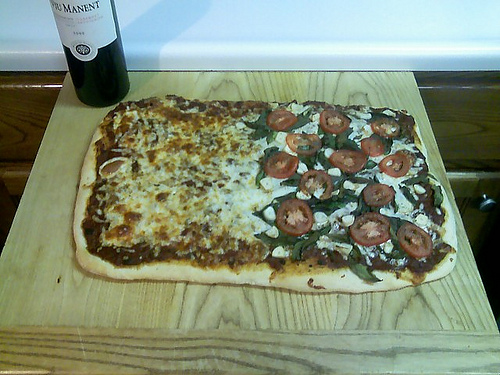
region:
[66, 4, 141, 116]
wine bottle on table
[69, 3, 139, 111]
wine bottle is red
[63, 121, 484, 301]
brown crust of pizza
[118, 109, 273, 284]
yellow cheese on pizza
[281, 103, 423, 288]
red tomatoes on pizza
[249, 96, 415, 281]
green basil on pizza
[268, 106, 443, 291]
white nuts on pizza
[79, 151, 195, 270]
red sauce on pizza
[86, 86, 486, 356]
board is light brown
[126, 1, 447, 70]
white counter behind board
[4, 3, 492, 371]
rectangle shaped pizza and a bottle of wine on a large wooden board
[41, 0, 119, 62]
white label on a dark glass bottle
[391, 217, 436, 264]
slice of tomato and greens on rectangle pizza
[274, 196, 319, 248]
slice of tomato and greens on rectangle pizza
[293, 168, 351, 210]
slice of tomato and greens on rectangle pizza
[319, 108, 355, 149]
slice of tomato and greens on rectangle pizza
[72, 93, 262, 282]
half pizza with no slices of tomatoes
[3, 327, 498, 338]
seam where two pieces of wood are joined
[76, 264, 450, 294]
light crust on one side of the pizza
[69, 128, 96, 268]
light crust on one side of the pizza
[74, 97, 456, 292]
flatbread pizza with tomatoes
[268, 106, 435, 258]
sliced cherry tomatoes on pizza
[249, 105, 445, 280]
half of pizza with tomatoes and spinach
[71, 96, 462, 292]
half and half pizza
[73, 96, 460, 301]
square pizza on wood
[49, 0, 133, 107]
bottle of red wine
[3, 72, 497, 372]
wooden board with pizza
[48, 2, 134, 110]
wine bottle on board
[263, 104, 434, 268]
white cheese on pizza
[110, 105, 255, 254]
cheese on half pizza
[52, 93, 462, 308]
A pizza is in the foreground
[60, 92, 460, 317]
The pizza is fully cooked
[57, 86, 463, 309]
Pizza has two different sides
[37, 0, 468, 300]
A wine bottle near the pizza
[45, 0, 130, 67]
Wine bottle has a white label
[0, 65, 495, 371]
Pizza is on a wooden board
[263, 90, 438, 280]
Right side of the pizza has tomato toppings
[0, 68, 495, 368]
Wooden board is tan in color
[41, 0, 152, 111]
Wine bottle is dark colored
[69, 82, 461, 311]
Pizza is in the shape of a sqaure